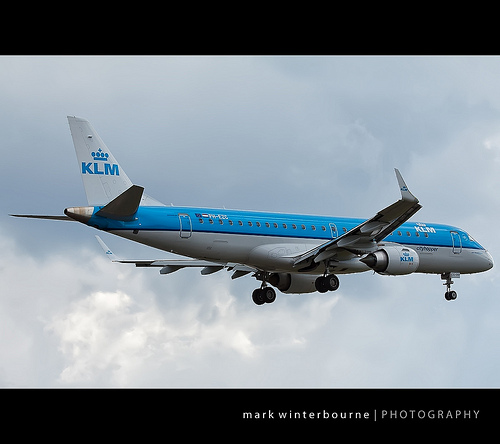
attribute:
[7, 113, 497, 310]
plane — blue, white, landing, cityhopper, outdoor scene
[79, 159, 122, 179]
klm letters — blue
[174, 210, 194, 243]
door — rear of windows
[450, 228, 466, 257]
door — cockpit door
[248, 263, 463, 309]
landing gear — down, in  down position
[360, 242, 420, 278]
engine — on right side, mounted to wing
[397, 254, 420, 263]
klm logo — displayed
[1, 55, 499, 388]
sky — cloudy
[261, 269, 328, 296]
engine — on left side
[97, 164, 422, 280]
jet flaps — in  down position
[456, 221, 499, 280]
nose of plane — in front